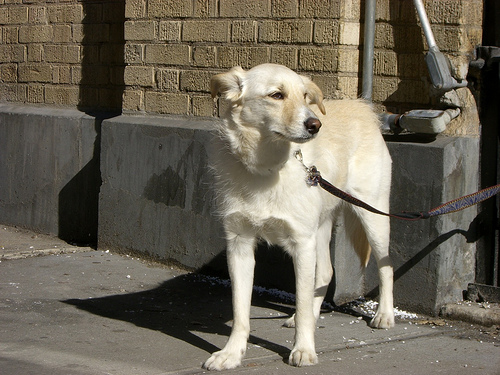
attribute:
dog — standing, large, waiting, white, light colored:
[197, 57, 407, 371]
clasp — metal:
[294, 144, 319, 190]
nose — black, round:
[305, 115, 324, 135]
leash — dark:
[294, 143, 499, 219]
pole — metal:
[356, 2, 383, 107]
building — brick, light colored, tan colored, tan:
[4, 6, 500, 321]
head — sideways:
[213, 52, 332, 151]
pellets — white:
[351, 290, 424, 332]